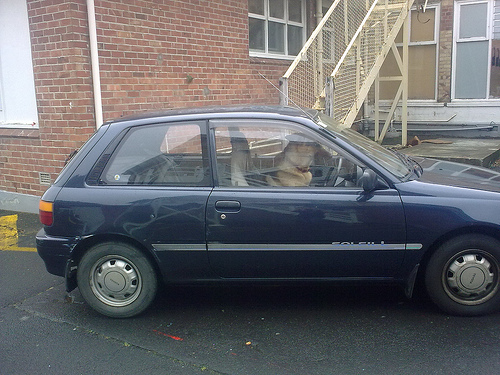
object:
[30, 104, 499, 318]
car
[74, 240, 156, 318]
back tire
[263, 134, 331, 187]
dog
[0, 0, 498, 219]
building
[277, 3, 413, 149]
stairway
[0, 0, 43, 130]
window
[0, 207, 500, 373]
street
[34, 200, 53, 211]
light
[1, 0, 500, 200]
exterior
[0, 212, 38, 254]
paint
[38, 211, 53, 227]
tail light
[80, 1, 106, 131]
pipe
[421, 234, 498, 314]
front tire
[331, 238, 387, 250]
name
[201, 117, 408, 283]
door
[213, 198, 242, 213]
handle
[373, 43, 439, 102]
window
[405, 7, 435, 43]
shade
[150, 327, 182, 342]
streak